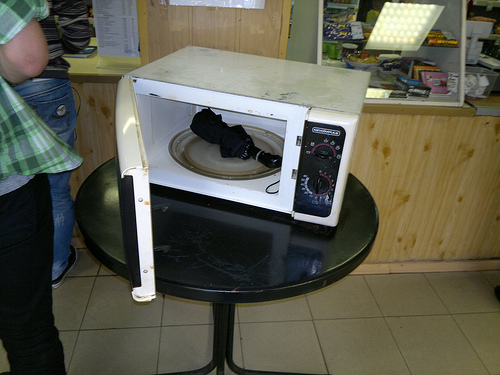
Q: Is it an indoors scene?
A: Yes, it is indoors.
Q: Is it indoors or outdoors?
A: It is indoors.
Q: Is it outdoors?
A: No, it is indoors.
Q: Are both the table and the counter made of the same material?
A: Yes, both the table and the counter are made of wood.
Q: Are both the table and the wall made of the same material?
A: Yes, both the table and the wall are made of wood.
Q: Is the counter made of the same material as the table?
A: Yes, both the counter and the table are made of wood.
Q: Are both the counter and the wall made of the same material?
A: Yes, both the counter and the wall are made of wood.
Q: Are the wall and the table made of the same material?
A: Yes, both the wall and the table are made of wood.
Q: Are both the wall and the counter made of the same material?
A: Yes, both the wall and the counter are made of wood.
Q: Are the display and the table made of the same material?
A: No, the display is made of glass and the table is made of wood.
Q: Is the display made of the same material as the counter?
A: No, the display is made of glass and the counter is made of wood.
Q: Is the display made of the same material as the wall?
A: No, the display is made of glass and the wall is made of wood.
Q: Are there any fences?
A: No, there are no fences.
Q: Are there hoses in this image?
A: No, there are no hoses.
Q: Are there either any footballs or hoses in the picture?
A: No, there are no hoses or footballs.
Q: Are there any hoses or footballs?
A: No, there are no hoses or footballs.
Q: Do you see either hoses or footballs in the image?
A: No, there are no hoses or footballs.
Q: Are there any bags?
A: No, there are no bags.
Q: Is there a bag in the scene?
A: No, there are no bags.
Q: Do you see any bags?
A: No, there are no bags.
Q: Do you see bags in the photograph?
A: No, there are no bags.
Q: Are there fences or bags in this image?
A: No, there are no bags or fences.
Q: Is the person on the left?
A: Yes, the person is on the left of the image.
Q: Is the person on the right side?
A: No, the person is on the left of the image.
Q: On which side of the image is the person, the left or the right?
A: The person is on the left of the image.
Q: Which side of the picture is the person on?
A: The person is on the left of the image.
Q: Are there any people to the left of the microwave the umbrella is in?
A: Yes, there is a person to the left of the microwave.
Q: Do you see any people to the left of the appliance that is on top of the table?
A: Yes, there is a person to the left of the microwave.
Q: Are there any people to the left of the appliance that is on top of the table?
A: Yes, there is a person to the left of the microwave.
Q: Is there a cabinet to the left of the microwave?
A: No, there is a person to the left of the microwave.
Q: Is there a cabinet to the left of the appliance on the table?
A: No, there is a person to the left of the microwave.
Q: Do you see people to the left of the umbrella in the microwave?
A: Yes, there is a person to the left of the umbrella.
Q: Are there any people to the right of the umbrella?
A: No, the person is to the left of the umbrella.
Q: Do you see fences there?
A: No, there are no fences.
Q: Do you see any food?
A: Yes, there is food.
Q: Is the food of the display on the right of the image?
A: Yes, the food is on the right of the image.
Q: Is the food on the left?
A: No, the food is on the right of the image.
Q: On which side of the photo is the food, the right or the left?
A: The food is on the right of the image.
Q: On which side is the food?
A: The food is on the right of the image.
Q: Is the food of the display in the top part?
A: Yes, the food is in the top of the image.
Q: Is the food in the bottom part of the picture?
A: No, the food is in the top of the image.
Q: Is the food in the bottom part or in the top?
A: The food is in the top of the image.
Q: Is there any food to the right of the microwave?
A: Yes, there is food to the right of the microwave.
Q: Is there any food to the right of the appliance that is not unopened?
A: Yes, there is food to the right of the microwave.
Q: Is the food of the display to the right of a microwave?
A: Yes, the food is to the right of a microwave.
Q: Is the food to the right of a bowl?
A: No, the food is to the right of a microwave.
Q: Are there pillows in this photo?
A: No, there are no pillows.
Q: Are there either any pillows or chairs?
A: No, there are no pillows or chairs.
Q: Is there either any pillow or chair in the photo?
A: No, there are no pillows or chairs.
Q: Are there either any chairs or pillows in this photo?
A: No, there are no pillows or chairs.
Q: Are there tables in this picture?
A: Yes, there is a table.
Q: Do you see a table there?
A: Yes, there is a table.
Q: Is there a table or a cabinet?
A: Yes, there is a table.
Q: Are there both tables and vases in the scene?
A: No, there is a table but no vases.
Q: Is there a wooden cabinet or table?
A: Yes, there is a wood table.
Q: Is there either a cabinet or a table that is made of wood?
A: Yes, the table is made of wood.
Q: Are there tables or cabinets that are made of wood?
A: Yes, the table is made of wood.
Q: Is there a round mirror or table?
A: Yes, there is a round table.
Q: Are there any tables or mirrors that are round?
A: Yes, the table is round.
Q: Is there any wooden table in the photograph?
A: Yes, there is a wood table.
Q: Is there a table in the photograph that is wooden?
A: Yes, there is a table that is wooden.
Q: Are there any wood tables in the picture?
A: Yes, there is a table that is made of wood.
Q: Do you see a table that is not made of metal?
A: Yes, there is a table that is made of wood.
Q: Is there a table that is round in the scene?
A: Yes, there is a round table.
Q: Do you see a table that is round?
A: Yes, there is a table that is round.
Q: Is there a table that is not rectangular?
A: Yes, there is a round table.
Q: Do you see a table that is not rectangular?
A: Yes, there is a round table.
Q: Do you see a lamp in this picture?
A: No, there are no lamps.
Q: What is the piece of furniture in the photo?
A: The piece of furniture is a table.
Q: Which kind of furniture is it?
A: The piece of furniture is a table.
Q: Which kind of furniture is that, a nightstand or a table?
A: This is a table.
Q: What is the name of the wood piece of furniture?
A: The piece of furniture is a table.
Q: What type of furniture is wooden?
A: The furniture is a table.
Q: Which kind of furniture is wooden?
A: The furniture is a table.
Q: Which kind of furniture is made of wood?
A: The furniture is a table.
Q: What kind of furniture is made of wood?
A: The furniture is a table.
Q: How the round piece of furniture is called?
A: The piece of furniture is a table.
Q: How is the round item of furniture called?
A: The piece of furniture is a table.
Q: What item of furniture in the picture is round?
A: The piece of furniture is a table.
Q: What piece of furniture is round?
A: The piece of furniture is a table.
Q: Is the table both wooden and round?
A: Yes, the table is wooden and round.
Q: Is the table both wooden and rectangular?
A: No, the table is wooden but round.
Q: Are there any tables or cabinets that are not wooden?
A: No, there is a table but it is wooden.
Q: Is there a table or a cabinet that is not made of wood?
A: No, there is a table but it is made of wood.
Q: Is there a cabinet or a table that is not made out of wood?
A: No, there is a table but it is made of wood.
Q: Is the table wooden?
A: Yes, the table is wooden.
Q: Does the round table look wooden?
A: Yes, the table is wooden.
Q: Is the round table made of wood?
A: Yes, the table is made of wood.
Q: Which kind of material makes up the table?
A: The table is made of wood.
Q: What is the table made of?
A: The table is made of wood.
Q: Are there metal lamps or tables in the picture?
A: No, there is a table but it is wooden.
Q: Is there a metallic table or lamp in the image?
A: No, there is a table but it is wooden.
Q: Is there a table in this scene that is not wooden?
A: No, there is a table but it is wooden.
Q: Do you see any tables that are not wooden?
A: No, there is a table but it is wooden.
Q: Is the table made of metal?
A: No, the table is made of wood.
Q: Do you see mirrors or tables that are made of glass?
A: No, there is a table but it is made of wood.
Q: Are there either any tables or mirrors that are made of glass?
A: No, there is a table but it is made of wood.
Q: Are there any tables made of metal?
A: No, there is a table but it is made of wood.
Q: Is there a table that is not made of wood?
A: No, there is a table but it is made of wood.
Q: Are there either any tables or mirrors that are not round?
A: No, there is a table but it is round.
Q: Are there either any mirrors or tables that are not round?
A: No, there is a table but it is round.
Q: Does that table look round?
A: Yes, the table is round.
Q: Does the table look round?
A: Yes, the table is round.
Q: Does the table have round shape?
A: Yes, the table is round.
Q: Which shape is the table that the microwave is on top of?
A: The table is round.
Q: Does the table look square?
A: No, the table is round.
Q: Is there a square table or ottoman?
A: No, there is a table but it is round.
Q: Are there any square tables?
A: No, there is a table but it is round.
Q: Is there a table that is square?
A: No, there is a table but it is round.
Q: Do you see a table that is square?
A: No, there is a table but it is round.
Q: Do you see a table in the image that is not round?
A: No, there is a table but it is round.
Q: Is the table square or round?
A: The table is round.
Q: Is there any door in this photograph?
A: Yes, there is a door.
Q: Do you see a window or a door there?
A: Yes, there is a door.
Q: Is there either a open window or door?
A: Yes, there is an open door.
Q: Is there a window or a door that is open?
A: Yes, the door is open.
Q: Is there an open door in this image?
A: Yes, there is an open door.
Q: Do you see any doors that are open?
A: Yes, there is a door that is open.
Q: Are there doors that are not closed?
A: Yes, there is a open door.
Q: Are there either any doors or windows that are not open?
A: No, there is a door but it is open.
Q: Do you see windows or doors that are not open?
A: No, there is a door but it is open.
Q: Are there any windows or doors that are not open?
A: No, there is a door but it is open.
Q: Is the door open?
A: Yes, the door is open.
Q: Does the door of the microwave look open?
A: Yes, the door is open.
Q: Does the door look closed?
A: No, the door is open.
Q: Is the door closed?
A: No, the door is open.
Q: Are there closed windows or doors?
A: No, there is a door but it is open.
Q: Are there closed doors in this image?
A: No, there is a door but it is open.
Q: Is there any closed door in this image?
A: No, there is a door but it is open.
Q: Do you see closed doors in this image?
A: No, there is a door but it is open.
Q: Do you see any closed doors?
A: No, there is a door but it is open.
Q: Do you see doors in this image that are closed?
A: No, there is a door but it is open.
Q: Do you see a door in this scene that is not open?
A: No, there is a door but it is open.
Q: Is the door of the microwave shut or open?
A: The door is open.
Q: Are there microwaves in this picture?
A: Yes, there is a microwave.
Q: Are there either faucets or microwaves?
A: Yes, there is a microwave.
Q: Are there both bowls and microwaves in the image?
A: No, there is a microwave but no bowls.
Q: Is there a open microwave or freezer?
A: Yes, there is an open microwave.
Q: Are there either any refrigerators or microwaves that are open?
A: Yes, the microwave is open.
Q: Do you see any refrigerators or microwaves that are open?
A: Yes, the microwave is open.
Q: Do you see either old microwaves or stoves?
A: Yes, there is an old microwave.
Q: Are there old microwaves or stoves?
A: Yes, there is an old microwave.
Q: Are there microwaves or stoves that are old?
A: Yes, the microwave is old.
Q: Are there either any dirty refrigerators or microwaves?
A: Yes, there is a dirty microwave.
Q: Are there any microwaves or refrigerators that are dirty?
A: Yes, the microwave is dirty.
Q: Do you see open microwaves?
A: Yes, there is an open microwave.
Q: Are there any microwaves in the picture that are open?
A: Yes, there is a microwave that is open.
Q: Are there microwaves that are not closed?
A: Yes, there is a open microwave.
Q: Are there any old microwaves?
A: Yes, there is an old microwave.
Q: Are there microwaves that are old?
A: Yes, there is a microwave that is old.